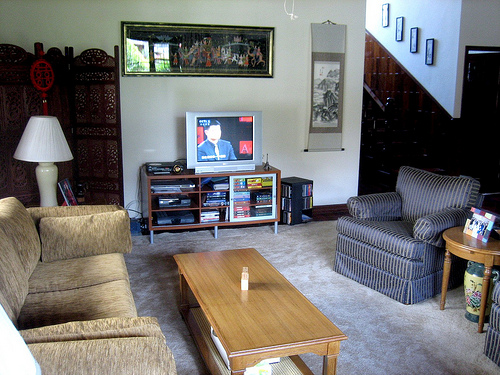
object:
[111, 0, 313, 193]
wall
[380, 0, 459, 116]
wall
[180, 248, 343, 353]
table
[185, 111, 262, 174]
tv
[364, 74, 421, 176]
stairs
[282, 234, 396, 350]
floor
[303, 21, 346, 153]
art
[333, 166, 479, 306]
chair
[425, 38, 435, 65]
pictures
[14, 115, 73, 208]
lamp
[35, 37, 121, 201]
room divider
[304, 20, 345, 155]
scroll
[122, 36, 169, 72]
windows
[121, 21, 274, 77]
art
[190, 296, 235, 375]
shelf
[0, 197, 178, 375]
couch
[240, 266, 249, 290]
bottle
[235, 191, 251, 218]
books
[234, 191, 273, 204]
shelf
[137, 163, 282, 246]
stand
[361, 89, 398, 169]
railing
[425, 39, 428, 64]
frames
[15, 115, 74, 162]
lampshade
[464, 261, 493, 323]
vase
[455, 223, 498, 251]
table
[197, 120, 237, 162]
man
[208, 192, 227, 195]
tapes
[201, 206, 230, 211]
shelf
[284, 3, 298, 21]
rope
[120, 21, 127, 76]
frame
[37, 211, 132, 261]
cushion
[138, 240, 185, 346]
carpet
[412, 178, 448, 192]
stripes